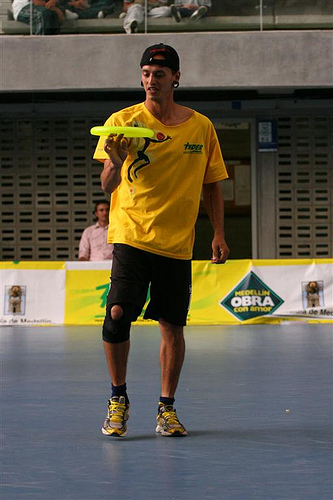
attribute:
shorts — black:
[101, 240, 193, 346]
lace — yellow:
[107, 396, 126, 422]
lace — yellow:
[159, 408, 181, 427]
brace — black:
[101, 302, 132, 344]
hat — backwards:
[139, 41, 181, 86]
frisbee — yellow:
[87, 124, 153, 138]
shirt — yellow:
[91, 99, 229, 259]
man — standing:
[90, 41, 228, 438]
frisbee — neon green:
[89, 125, 155, 139]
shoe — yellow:
[99, 392, 130, 438]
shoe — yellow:
[154, 400, 186, 436]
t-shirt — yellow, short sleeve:
[91, 100, 229, 260]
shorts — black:
[104, 242, 192, 326]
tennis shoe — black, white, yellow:
[99, 393, 130, 438]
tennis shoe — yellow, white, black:
[154, 400, 188, 436]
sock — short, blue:
[109, 382, 128, 403]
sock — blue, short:
[155, 395, 175, 413]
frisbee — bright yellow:
[89, 124, 154, 140]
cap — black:
[139, 40, 180, 86]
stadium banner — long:
[1, 257, 320, 327]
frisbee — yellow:
[67, 96, 172, 140]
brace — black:
[84, 283, 150, 353]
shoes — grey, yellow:
[93, 384, 251, 458]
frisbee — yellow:
[87, 109, 197, 154]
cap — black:
[128, 30, 206, 88]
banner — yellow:
[51, 247, 258, 334]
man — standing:
[86, 219, 127, 268]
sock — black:
[100, 377, 139, 400]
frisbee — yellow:
[75, 114, 193, 170]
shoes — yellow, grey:
[72, 375, 231, 433]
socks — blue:
[102, 379, 198, 418]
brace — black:
[82, 279, 134, 375]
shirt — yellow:
[95, 89, 262, 265]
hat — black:
[136, 39, 187, 79]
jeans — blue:
[28, 11, 58, 35]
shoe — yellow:
[147, 399, 194, 436]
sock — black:
[96, 381, 151, 399]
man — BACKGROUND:
[76, 199, 114, 260]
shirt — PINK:
[77, 222, 112, 260]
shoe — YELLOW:
[102, 396, 129, 440]